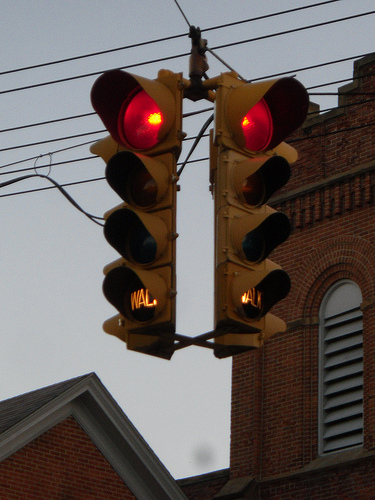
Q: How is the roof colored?
A: Gray.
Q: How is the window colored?
A: White.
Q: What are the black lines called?
A: Power or electricity cords.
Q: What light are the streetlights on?
A: Red.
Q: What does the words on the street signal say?
A: Walk.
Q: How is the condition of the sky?
A: Overcast.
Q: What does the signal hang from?
A: The black lines.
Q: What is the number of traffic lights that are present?
A: Two.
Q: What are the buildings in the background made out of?
A: Bricks.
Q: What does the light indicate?
A: Stop.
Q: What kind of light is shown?
A: Traffic.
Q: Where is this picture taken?
A: Street.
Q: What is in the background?
A: Building.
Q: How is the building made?
A: Of brick.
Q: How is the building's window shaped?
A: Elongated oval.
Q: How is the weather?
A: Overcast.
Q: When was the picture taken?
A: Early evening.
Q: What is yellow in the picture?
A: Traffic lights.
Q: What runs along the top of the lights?
A: Electrical wires.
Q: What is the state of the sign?
A: It's walk.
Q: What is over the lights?
A: It's wire.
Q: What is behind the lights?
A: A brick building.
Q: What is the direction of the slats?
A: It's downwards.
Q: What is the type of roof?
A: It's pointed.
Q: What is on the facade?
A: It's white molding.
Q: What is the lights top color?
A: It's red.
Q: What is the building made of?
A: It's brick.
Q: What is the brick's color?
A: It's red.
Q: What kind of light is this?
A: Stop light.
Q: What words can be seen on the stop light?
A: Walk.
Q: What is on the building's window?
A: White shutters.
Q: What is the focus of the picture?
A: A traffic light.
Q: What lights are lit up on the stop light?
A: Red and Walk.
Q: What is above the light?
A: Lines.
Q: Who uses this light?
A: Drivers.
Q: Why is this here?
A: To prevent accidents.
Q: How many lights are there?
A: 2.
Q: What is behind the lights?
A: Buildings.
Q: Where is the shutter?
A: On building.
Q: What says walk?
A: The light.